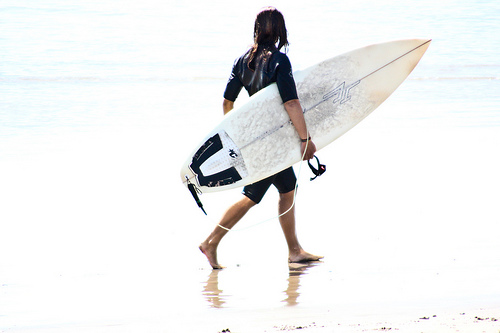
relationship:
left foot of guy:
[284, 246, 328, 267] [198, 5, 327, 270]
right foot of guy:
[192, 236, 231, 271] [198, 5, 327, 270]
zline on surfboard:
[175, 127, 317, 235] [177, 35, 436, 201]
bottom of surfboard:
[178, 123, 246, 192] [177, 35, 436, 201]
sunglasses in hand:
[309, 154, 328, 183] [303, 139, 320, 162]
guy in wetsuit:
[198, 5, 327, 270] [220, 47, 300, 204]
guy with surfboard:
[198, 2, 331, 275] [177, 35, 436, 201]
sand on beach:
[234, 306, 500, 332] [13, 142, 497, 332]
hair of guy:
[242, 6, 292, 68] [198, 2, 331, 275]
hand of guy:
[303, 139, 320, 162] [198, 5, 327, 270]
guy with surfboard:
[198, 5, 327, 270] [177, 35, 436, 201]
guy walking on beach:
[198, 5, 327, 270] [13, 142, 497, 332]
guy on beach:
[198, 5, 327, 270] [13, 142, 497, 332]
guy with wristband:
[198, 5, 327, 270] [297, 133, 315, 146]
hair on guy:
[242, 6, 292, 68] [198, 5, 327, 270]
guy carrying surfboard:
[198, 5, 327, 270] [177, 35, 436, 201]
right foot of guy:
[198, 244, 228, 270] [198, 5, 327, 270]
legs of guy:
[205, 165, 306, 245] [198, 5, 327, 270]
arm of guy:
[276, 64, 314, 143] [198, 5, 327, 270]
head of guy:
[254, 7, 286, 44] [198, 5, 327, 270]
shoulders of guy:
[229, 48, 298, 76] [198, 5, 327, 270]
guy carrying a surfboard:
[198, 5, 327, 270] [177, 35, 436, 201]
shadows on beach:
[205, 263, 309, 312] [13, 142, 497, 332]